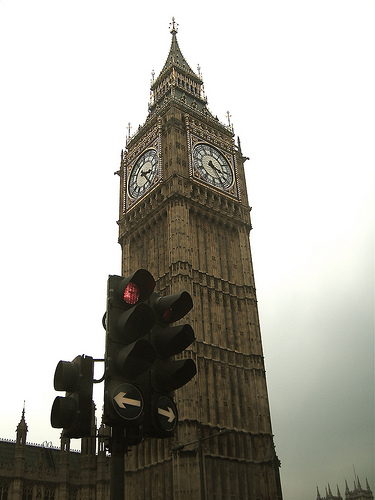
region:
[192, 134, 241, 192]
clock face on tower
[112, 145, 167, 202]
clock face on tower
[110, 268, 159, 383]
traffic signal on the pole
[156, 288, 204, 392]
traffic signal on the pol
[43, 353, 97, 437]
traffic signal on the pol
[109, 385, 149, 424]
traffic arrow attached to signal light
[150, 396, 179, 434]
traffic arrow attached to signal light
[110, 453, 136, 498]
pole attached to traffic signal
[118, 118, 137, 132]
cross attached to the building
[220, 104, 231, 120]
cross attached to the building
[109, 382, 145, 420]
Black circle with a white arrow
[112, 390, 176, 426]
Two white arrows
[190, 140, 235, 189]
Black and white analog clock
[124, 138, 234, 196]
Two circular analog clocks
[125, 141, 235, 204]
Two large analog clocks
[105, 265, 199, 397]
Two black traffic light fixtures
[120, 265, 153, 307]
Red light on a traffic light fixture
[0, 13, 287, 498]
Large building with a clock tower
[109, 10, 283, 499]
Tower with two clocks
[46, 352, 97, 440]
Small black traffic light fixture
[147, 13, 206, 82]
steeple on top of tower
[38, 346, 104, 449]
black traffic light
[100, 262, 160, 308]
red traffiic light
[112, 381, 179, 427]
white arrow on black sign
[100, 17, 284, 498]
stone tower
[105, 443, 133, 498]
metal traffic light supportpole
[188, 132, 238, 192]
clocks on top of tower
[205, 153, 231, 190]
black hands on clock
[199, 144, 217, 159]
roman numeral on clock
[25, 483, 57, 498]
windows on side of building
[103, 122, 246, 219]
two round clocks in photo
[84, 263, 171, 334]
red light in photo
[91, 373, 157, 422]
arrow pointing to the left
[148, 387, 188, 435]
arrow pointing to the right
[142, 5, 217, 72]
top of the building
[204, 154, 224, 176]
hands on the clock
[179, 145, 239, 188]
white clock face in photo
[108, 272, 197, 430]
black metal traffic traffic lights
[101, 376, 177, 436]
left and right turn only lights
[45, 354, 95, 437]
a two light traffic light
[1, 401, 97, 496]
a portion of the Palace of Westminster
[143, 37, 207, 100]
the home of the bell Big Ben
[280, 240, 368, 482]
a darkening cloud to the right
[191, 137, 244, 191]
the face of the clock in Elizabeth Tower